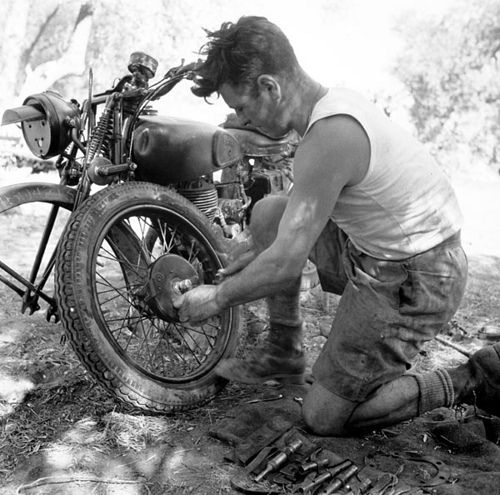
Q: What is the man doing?
A: Fixing a motorcycle wheel.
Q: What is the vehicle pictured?
A: A motorcycle.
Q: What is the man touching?
A: A motorcycle wheel.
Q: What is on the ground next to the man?
A: Tools.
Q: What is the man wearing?
A: A white tank top.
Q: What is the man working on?
A: A wheel.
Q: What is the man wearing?
A: Shorts.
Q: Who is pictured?
A: A man.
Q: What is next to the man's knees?
A: Metal tools.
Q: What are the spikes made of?
A: Silver.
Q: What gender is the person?
A: Male.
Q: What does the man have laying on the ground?
A: Tools.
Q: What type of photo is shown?
A: Black and white.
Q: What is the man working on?
A: Motorcycle.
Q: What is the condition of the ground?
A: Bare.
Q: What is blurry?
A: The background.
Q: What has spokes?
A: The wheel.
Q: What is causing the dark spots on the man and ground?
A: Shadows.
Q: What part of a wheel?
A: Spokes.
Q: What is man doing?
A: Kneeling.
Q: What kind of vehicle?
A: Motorcycle.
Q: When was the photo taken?
A: Daytime.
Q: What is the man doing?
A: Repairs.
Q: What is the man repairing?
A: A motorbike.